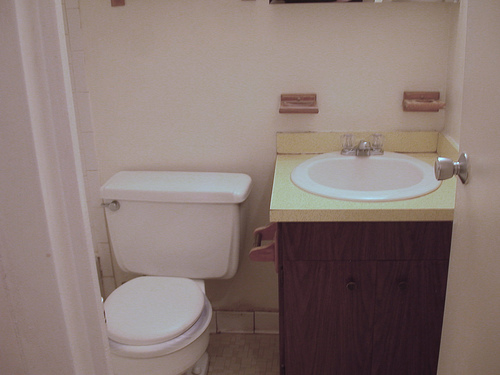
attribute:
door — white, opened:
[468, 40, 499, 159]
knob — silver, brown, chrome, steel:
[432, 152, 474, 191]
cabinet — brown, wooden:
[282, 224, 440, 375]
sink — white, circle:
[296, 149, 433, 199]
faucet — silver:
[333, 133, 392, 156]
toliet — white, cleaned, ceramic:
[96, 264, 221, 373]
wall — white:
[135, 28, 239, 96]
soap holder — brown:
[269, 87, 322, 116]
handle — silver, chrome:
[451, 154, 474, 184]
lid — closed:
[105, 286, 200, 329]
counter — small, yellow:
[279, 193, 307, 216]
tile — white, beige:
[239, 308, 256, 326]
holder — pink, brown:
[255, 244, 272, 262]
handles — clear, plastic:
[343, 131, 379, 141]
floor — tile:
[226, 337, 272, 372]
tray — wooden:
[281, 103, 315, 113]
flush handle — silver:
[99, 195, 123, 209]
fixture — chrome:
[350, 147, 373, 154]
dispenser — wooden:
[255, 226, 263, 247]